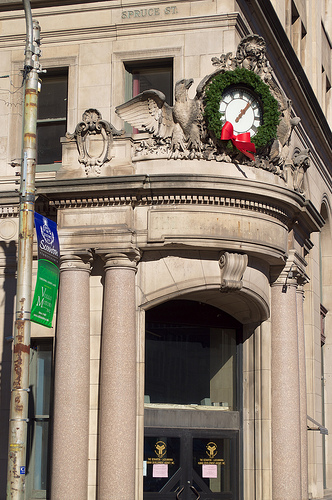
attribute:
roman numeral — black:
[238, 89, 242, 98]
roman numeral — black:
[229, 90, 234, 99]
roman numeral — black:
[221, 99, 230, 105]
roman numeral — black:
[252, 124, 258, 132]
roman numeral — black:
[217, 111, 225, 115]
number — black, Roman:
[252, 112, 265, 121]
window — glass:
[91, 28, 192, 152]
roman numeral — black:
[236, 90, 247, 99]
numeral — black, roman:
[251, 102, 263, 112]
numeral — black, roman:
[219, 113, 226, 120]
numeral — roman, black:
[251, 121, 260, 129]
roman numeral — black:
[245, 96, 253, 106]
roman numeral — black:
[226, 85, 236, 101]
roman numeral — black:
[236, 89, 245, 99]